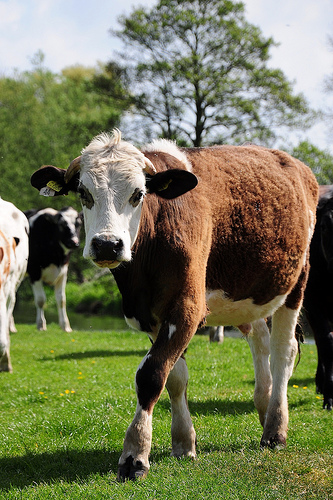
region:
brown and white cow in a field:
[25, 102, 318, 477]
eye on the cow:
[126, 182, 140, 200]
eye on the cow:
[69, 177, 96, 204]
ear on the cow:
[23, 155, 71, 213]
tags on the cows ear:
[37, 178, 64, 201]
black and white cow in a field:
[32, 203, 76, 327]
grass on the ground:
[22, 389, 85, 439]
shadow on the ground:
[7, 437, 87, 491]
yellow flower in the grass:
[51, 370, 79, 399]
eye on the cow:
[76, 181, 86, 203]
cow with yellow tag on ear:
[23, 164, 70, 207]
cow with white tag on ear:
[33, 180, 66, 206]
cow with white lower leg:
[133, 415, 151, 494]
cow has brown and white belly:
[217, 286, 300, 329]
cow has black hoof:
[119, 467, 160, 487]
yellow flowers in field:
[33, 386, 105, 403]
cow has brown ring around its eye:
[121, 184, 139, 208]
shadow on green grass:
[40, 445, 123, 492]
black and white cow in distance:
[43, 223, 70, 289]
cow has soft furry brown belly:
[225, 230, 296, 279]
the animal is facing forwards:
[16, 129, 321, 487]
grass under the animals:
[1, 322, 328, 498]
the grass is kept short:
[1, 320, 322, 496]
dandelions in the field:
[22, 333, 106, 411]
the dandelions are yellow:
[20, 330, 111, 421]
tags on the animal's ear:
[25, 159, 76, 207]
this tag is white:
[33, 183, 52, 199]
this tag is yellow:
[41, 176, 66, 193]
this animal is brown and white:
[23, 137, 329, 491]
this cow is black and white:
[21, 208, 82, 336]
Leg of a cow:
[161, 309, 205, 467]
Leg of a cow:
[115, 300, 193, 492]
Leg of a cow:
[260, 287, 307, 455]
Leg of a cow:
[238, 309, 275, 448]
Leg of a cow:
[52, 273, 79, 342]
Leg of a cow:
[27, 271, 47, 341]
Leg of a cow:
[0, 294, 25, 377]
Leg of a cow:
[215, 326, 230, 345]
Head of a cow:
[25, 126, 208, 274]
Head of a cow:
[46, 196, 93, 250]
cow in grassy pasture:
[61, 160, 301, 484]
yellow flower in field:
[59, 393, 70, 403]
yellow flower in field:
[72, 389, 77, 401]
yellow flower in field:
[43, 394, 48, 403]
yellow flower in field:
[37, 389, 44, 398]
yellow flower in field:
[288, 378, 300, 397]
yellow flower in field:
[312, 395, 321, 408]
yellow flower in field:
[300, 385, 310, 393]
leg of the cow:
[115, 419, 159, 491]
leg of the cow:
[164, 411, 199, 459]